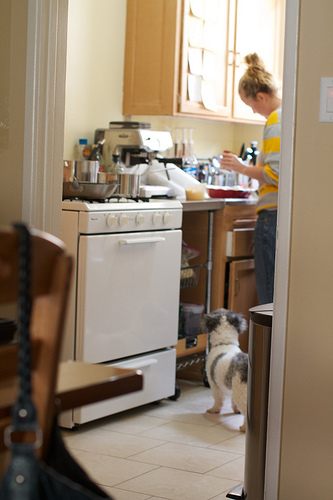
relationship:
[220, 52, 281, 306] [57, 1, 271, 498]
woman standing in kitchen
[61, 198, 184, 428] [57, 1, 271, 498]
stove in kitchen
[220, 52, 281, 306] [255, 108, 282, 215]
woman wearing top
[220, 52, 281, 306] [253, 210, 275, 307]
woman wearing pants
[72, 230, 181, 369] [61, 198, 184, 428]
door on stove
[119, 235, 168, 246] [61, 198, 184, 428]
handle on stove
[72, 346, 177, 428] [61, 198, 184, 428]
drawer on stove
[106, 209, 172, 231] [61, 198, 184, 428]
knobs on stove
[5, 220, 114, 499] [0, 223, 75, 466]
purse hanging on chair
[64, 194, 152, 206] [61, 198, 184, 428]
burners on stove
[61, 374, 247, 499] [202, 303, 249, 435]
floor under dog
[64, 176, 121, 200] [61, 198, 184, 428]
frying pan on stove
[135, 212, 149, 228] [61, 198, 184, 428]
knob on stove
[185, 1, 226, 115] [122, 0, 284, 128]
sticky notes on cabinets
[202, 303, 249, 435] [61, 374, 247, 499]
dog standing on floor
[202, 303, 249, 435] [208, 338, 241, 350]
dog wearing collar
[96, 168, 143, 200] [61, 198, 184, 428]
pot on stove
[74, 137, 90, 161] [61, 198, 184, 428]
bottle next to stove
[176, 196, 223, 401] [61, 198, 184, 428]
rack next to stove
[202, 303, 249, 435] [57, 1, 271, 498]
dog in kitchen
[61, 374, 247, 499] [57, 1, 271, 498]
floor in kitchen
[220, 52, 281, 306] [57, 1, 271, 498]
woman in kitchen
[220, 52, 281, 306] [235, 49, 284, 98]
woman has hair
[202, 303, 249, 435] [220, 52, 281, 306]
dog looking at woman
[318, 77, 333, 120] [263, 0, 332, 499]
light switch on wall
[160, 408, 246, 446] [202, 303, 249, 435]
shadow of dog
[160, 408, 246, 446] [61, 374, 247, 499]
shadow on floor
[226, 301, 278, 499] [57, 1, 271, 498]
trash can in kitchen